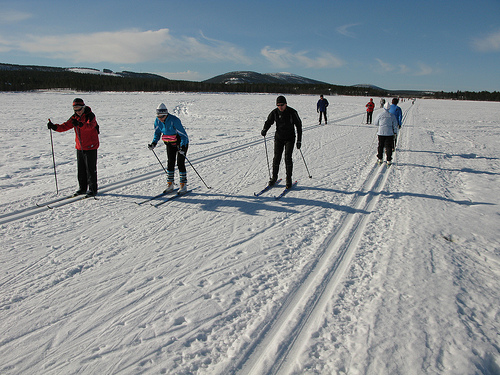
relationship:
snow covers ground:
[0, 88, 498, 374] [26, 195, 481, 334]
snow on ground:
[142, 269, 460, 331] [0, 77, 497, 373]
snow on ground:
[0, 88, 498, 374] [14, 91, 474, 364]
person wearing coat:
[48, 96, 116, 203] [49, 107, 101, 152]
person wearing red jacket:
[360, 92, 376, 125] [363, 101, 377, 113]